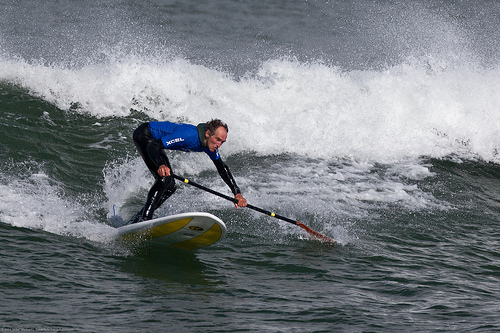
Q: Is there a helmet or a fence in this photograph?
A: No, there are no fences or helmets.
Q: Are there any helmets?
A: No, there are no helmets.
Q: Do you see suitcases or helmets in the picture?
A: No, there are no helmets or suitcases.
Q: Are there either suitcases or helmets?
A: No, there are no helmets or suitcases.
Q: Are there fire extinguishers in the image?
A: No, there are no fire extinguishers.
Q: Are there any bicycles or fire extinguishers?
A: No, there are no fire extinguishers or bicycles.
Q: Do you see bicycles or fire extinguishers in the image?
A: No, there are no fire extinguishers or bicycles.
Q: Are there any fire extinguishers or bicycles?
A: No, there are no fire extinguishers or bicycles.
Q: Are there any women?
A: No, there are no women.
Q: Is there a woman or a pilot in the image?
A: No, there are no women or pilots.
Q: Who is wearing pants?
A: The man is wearing pants.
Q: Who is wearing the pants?
A: The man is wearing pants.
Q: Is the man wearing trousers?
A: Yes, the man is wearing trousers.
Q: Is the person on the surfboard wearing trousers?
A: Yes, the man is wearing trousers.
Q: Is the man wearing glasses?
A: No, the man is wearing trousers.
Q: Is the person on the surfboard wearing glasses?
A: No, the man is wearing trousers.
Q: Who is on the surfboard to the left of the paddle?
A: The man is on the surf board.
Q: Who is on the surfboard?
A: The man is on the surf board.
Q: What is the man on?
A: The man is on the surfboard.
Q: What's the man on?
A: The man is on the surfboard.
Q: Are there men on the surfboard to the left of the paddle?
A: Yes, there is a man on the surfboard.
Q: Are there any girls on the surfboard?
A: No, there is a man on the surfboard.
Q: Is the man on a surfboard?
A: Yes, the man is on a surfboard.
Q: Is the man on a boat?
A: No, the man is on a surfboard.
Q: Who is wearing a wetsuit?
A: The man is wearing a wetsuit.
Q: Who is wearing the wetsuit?
A: The man is wearing a wetsuit.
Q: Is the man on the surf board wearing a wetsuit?
A: Yes, the man is wearing a wetsuit.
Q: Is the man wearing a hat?
A: No, the man is wearing a wetsuit.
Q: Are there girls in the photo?
A: No, there are no girls.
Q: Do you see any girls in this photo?
A: No, there are no girls.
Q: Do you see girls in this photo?
A: No, there are no girls.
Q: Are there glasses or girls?
A: No, there are no girls or glasses.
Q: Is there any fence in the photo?
A: No, there are no fences.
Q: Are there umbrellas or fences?
A: No, there are no fences or umbrellas.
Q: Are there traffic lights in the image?
A: No, there are no traffic lights.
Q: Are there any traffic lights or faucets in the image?
A: No, there are no traffic lights or faucets.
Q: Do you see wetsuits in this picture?
A: Yes, there is a wetsuit.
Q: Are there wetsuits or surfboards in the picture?
A: Yes, there is a wetsuit.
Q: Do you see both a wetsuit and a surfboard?
A: Yes, there are both a wetsuit and a surfboard.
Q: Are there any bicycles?
A: No, there are no bicycles.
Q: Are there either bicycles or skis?
A: No, there are no bicycles or skis.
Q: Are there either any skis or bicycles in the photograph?
A: No, there are no bicycles or skis.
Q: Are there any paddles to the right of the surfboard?
A: Yes, there is a paddle to the right of the surfboard.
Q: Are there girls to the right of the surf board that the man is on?
A: No, there is a paddle to the right of the surfboard.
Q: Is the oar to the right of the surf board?
A: Yes, the oar is to the right of the surf board.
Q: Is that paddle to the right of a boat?
A: No, the paddle is to the right of the surf board.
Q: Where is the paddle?
A: The paddle is in the water.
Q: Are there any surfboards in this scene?
A: Yes, there is a surfboard.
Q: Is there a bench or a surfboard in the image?
A: Yes, there is a surfboard.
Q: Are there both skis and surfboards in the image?
A: No, there is a surfboard but no skis.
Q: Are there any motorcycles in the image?
A: No, there are no motorcycles.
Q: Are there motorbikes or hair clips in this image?
A: No, there are no motorbikes or hair clips.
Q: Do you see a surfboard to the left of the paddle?
A: Yes, there is a surfboard to the left of the paddle.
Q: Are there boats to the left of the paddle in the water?
A: No, there is a surfboard to the left of the oar.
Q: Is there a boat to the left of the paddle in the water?
A: No, there is a surfboard to the left of the oar.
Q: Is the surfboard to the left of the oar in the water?
A: Yes, the surfboard is to the left of the oar.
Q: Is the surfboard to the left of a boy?
A: No, the surfboard is to the left of the oar.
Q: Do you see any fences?
A: No, there are no fences.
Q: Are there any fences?
A: No, there are no fences.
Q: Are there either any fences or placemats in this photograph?
A: No, there are no fences or placemats.